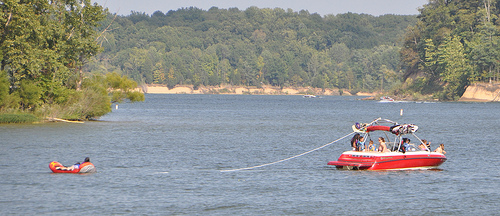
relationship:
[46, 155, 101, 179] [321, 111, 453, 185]
object attached to boat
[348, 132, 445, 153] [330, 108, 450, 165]
people on boat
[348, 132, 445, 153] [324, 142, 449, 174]
people on boat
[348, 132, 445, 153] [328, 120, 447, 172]
people on boat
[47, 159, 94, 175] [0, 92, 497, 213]
float in water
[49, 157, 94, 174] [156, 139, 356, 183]
float in water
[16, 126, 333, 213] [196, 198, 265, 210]
water has ripples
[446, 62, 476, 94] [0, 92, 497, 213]
bush on water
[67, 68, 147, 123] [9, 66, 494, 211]
bush next to water